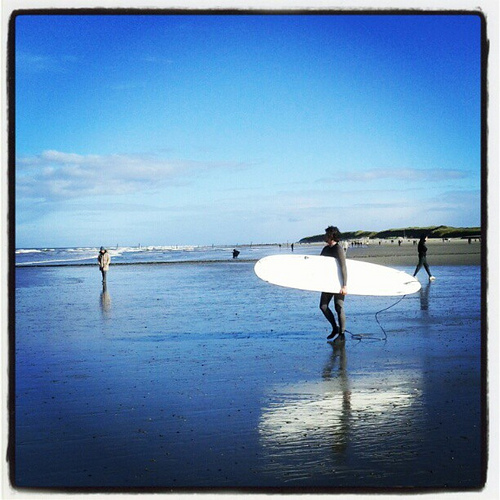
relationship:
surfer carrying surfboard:
[317, 226, 356, 342] [249, 251, 429, 309]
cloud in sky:
[14, 147, 165, 199] [219, 14, 476, 102]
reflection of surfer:
[328, 336, 354, 373] [317, 226, 356, 342]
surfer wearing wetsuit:
[317, 226, 356, 342] [323, 244, 347, 322]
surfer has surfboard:
[317, 226, 356, 342] [249, 251, 429, 309]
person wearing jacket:
[93, 247, 112, 273] [94, 255, 109, 269]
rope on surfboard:
[371, 302, 405, 333] [249, 251, 429, 309]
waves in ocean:
[28, 253, 89, 277] [14, 270, 103, 482]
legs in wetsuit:
[319, 294, 358, 334] [323, 244, 347, 322]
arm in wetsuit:
[334, 243, 353, 282] [323, 244, 347, 322]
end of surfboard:
[405, 270, 425, 299] [249, 251, 429, 309]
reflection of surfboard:
[284, 390, 408, 429] [249, 251, 429, 309]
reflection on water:
[328, 336, 354, 373] [231, 352, 298, 382]